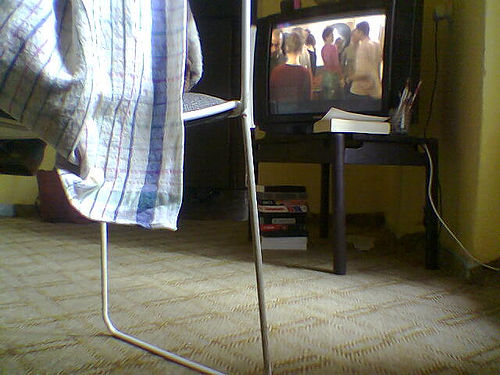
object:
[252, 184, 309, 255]
vhs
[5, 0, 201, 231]
towel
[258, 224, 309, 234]
books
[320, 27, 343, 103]
people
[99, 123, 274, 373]
silver bottom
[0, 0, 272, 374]
chair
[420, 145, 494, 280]
white wire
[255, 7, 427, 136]
television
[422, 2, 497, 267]
wall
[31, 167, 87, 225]
purse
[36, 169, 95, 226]
laptop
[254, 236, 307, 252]
books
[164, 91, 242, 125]
seat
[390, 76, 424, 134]
utensils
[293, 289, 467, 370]
rug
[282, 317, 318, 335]
line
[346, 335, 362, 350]
line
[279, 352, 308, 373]
line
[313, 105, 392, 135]
book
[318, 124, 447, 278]
chair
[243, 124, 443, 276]
stand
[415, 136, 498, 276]
cord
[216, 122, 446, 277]
table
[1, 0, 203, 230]
plaid cloth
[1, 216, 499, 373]
floor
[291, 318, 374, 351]
square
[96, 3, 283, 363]
frame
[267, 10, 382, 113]
tv screen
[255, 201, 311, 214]
movie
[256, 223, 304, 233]
movie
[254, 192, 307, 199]
movie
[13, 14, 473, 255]
background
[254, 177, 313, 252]
stack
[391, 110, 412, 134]
cup